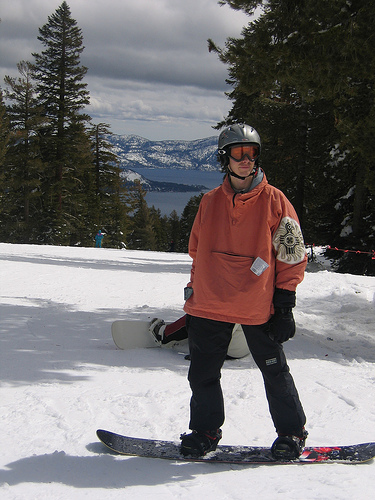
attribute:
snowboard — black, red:
[94, 423, 372, 466]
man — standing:
[179, 122, 321, 459]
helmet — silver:
[218, 123, 264, 151]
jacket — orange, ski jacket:
[181, 181, 308, 324]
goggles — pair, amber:
[226, 140, 259, 163]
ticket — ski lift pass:
[250, 254, 273, 278]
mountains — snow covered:
[98, 122, 232, 174]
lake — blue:
[129, 164, 230, 219]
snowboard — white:
[111, 315, 167, 353]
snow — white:
[4, 239, 373, 499]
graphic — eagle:
[270, 216, 308, 267]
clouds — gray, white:
[3, 5, 245, 127]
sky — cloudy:
[2, 0, 289, 140]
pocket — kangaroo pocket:
[211, 246, 263, 297]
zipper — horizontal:
[215, 248, 254, 259]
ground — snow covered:
[3, 240, 374, 499]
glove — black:
[272, 286, 297, 343]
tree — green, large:
[34, 6, 88, 250]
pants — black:
[184, 314, 309, 440]